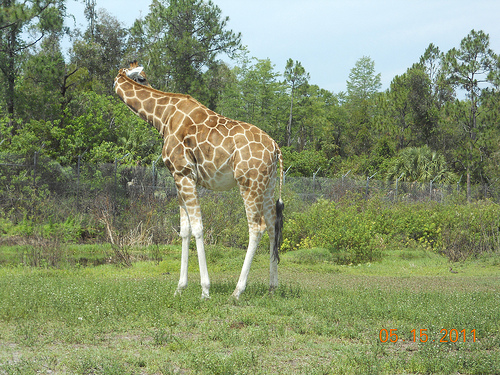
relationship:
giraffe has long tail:
[111, 59, 286, 302] [272, 149, 287, 269]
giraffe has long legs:
[111, 59, 286, 302] [160, 168, 279, 306]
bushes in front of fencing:
[1, 198, 499, 267] [2, 149, 496, 203]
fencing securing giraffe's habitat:
[2, 149, 496, 203] [1, 1, 500, 373]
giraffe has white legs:
[111, 59, 286, 302] [160, 168, 279, 306]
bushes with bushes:
[1, 198, 499, 267] [1, 198, 499, 267]